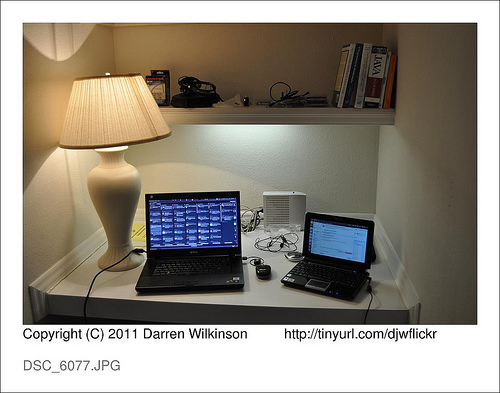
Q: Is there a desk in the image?
A: Yes, there is a desk.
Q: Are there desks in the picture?
A: Yes, there is a desk.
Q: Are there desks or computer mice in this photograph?
A: Yes, there is a desk.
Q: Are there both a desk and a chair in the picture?
A: No, there is a desk but no chairs.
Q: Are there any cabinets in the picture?
A: No, there are no cabinets.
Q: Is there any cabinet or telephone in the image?
A: No, there are no cabinets or phones.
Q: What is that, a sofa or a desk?
A: That is a desk.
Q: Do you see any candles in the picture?
A: No, there are no candles.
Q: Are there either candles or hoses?
A: No, there are no candles or hoses.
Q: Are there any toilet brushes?
A: No, there are no toilet brushes.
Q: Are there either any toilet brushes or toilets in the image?
A: No, there are no toilet brushes or toilets.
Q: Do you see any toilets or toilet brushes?
A: No, there are no toilet brushes or toilets.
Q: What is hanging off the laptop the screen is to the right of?
A: The wire is hanging off the laptop computer.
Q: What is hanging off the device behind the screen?
A: The wire is hanging off the laptop computer.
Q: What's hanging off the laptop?
A: The wire is hanging off the laptop computer.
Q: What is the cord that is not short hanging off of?
A: The wire is hanging off the laptop.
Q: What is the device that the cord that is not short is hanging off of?
A: The device is a laptop.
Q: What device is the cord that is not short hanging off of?
A: The wire is hanging off the laptop.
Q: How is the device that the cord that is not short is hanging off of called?
A: The device is a laptop.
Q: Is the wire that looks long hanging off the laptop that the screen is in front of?
A: Yes, the wire is hanging off the laptop.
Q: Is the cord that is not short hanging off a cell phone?
A: No, the cord is hanging off the laptop.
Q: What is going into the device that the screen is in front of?
A: The cord is going into the laptop.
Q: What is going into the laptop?
A: The cord is going into the laptop.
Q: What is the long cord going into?
A: The cord is going into the laptop.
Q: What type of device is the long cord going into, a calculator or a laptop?
A: The wire is going into a laptop.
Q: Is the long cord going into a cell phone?
A: No, the wire is going into the laptop.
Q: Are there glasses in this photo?
A: No, there are no glasses.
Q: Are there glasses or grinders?
A: No, there are no glasses or grinders.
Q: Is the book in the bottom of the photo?
A: No, the book is in the top of the image.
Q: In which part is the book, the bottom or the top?
A: The book is in the top of the image.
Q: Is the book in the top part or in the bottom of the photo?
A: The book is in the top of the image.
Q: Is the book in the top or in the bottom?
A: The book is in the top of the image.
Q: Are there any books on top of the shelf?
A: Yes, there is a book on top of the shelf.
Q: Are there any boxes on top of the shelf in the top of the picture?
A: No, there is a book on top of the shelf.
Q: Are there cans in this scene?
A: No, there are no cans.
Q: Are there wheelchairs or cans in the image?
A: No, there are no cans or wheelchairs.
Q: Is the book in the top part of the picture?
A: Yes, the book is in the top of the image.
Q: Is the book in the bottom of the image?
A: No, the book is in the top of the image.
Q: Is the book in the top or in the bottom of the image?
A: The book is in the top of the image.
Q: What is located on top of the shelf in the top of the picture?
A: The book is on top of the shelf.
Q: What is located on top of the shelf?
A: The book is on top of the shelf.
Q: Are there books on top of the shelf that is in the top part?
A: Yes, there is a book on top of the shelf.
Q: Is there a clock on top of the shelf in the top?
A: No, there is a book on top of the shelf.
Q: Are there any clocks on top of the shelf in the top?
A: No, there is a book on top of the shelf.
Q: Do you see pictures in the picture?
A: No, there are no pictures.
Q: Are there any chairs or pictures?
A: No, there are no pictures or chairs.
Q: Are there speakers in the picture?
A: No, there are no speakers.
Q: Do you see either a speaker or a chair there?
A: No, there are no speakers or chairs.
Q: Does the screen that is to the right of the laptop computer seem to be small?
A: Yes, the screen is small.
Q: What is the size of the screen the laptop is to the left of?
A: The screen is small.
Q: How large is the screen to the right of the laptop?
A: The screen is small.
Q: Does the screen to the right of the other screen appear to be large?
A: No, the screen is small.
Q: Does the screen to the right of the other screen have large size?
A: No, the screen is small.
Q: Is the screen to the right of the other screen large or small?
A: The screen is small.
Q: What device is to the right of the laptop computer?
A: The device is a screen.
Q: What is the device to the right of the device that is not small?
A: The device is a screen.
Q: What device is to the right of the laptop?
A: The device is a screen.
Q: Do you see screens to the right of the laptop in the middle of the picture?
A: Yes, there is a screen to the right of the laptop.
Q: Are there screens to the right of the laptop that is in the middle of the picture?
A: Yes, there is a screen to the right of the laptop.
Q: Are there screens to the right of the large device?
A: Yes, there is a screen to the right of the laptop.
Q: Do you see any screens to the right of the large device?
A: Yes, there is a screen to the right of the laptop.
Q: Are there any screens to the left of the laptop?
A: No, the screen is to the right of the laptop.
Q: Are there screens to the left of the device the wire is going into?
A: No, the screen is to the right of the laptop.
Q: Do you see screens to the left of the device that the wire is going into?
A: No, the screen is to the right of the laptop.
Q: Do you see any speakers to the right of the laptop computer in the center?
A: No, there is a screen to the right of the laptop.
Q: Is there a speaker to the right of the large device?
A: No, there is a screen to the right of the laptop.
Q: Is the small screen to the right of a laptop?
A: Yes, the screen is to the right of a laptop.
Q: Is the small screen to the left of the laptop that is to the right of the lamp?
A: No, the screen is to the right of the laptop.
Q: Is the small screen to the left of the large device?
A: No, the screen is to the right of the laptop.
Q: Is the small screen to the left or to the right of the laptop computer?
A: The screen is to the right of the laptop computer.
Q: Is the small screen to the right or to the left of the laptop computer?
A: The screen is to the right of the laptop computer.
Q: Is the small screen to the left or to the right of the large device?
A: The screen is to the right of the laptop computer.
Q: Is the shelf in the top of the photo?
A: Yes, the shelf is in the top of the image.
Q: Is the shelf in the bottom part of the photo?
A: No, the shelf is in the top of the image.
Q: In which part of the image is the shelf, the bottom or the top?
A: The shelf is in the top of the image.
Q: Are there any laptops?
A: Yes, there is a laptop.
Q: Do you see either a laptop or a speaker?
A: Yes, there is a laptop.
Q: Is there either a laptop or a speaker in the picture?
A: Yes, there is a laptop.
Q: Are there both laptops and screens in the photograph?
A: Yes, there are both a laptop and a screen.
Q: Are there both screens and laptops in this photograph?
A: Yes, there are both a laptop and a screen.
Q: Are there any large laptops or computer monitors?
A: Yes, there is a large laptop.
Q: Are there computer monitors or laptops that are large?
A: Yes, the laptop is large.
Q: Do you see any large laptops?
A: Yes, there is a large laptop.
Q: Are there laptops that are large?
A: Yes, there is a laptop that is large.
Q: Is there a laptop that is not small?
A: Yes, there is a large laptop.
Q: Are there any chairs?
A: No, there are no chairs.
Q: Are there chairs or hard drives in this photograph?
A: No, there are no chairs or hard drives.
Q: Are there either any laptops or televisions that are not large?
A: No, there is a laptop but it is large.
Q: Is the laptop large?
A: Yes, the laptop is large.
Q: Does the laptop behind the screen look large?
A: Yes, the laptop is large.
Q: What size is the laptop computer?
A: The laptop computer is large.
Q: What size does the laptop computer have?
A: The laptop computer has large size.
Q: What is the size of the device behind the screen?
A: The laptop computer is large.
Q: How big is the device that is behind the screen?
A: The laptop is large.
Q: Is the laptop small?
A: No, the laptop is large.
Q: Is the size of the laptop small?
A: No, the laptop is large.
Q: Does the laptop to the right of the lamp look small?
A: No, the laptop computer is large.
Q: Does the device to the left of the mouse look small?
A: No, the laptop computer is large.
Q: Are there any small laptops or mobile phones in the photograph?
A: No, there is a laptop but it is large.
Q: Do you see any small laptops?
A: No, there is a laptop but it is large.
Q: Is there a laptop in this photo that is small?
A: No, there is a laptop but it is large.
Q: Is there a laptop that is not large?
A: No, there is a laptop but it is large.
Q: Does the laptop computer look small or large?
A: The laptop computer is large.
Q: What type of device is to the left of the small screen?
A: The device is a laptop.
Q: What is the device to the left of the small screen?
A: The device is a laptop.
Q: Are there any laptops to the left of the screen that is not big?
A: Yes, there is a laptop to the left of the screen.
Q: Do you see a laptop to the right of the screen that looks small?
A: No, the laptop is to the left of the screen.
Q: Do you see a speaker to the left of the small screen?
A: No, there is a laptop to the left of the screen.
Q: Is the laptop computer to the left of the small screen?
A: Yes, the laptop computer is to the left of the screen.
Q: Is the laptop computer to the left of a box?
A: No, the laptop computer is to the left of the screen.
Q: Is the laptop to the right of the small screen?
A: No, the laptop is to the left of the screen.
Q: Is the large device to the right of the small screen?
A: No, the laptop is to the left of the screen.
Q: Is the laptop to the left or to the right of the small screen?
A: The laptop is to the left of the screen.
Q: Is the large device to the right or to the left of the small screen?
A: The laptop is to the left of the screen.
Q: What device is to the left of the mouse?
A: The device is a laptop.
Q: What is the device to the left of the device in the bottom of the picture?
A: The device is a laptop.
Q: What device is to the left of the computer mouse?
A: The device is a laptop.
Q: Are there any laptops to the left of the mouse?
A: Yes, there is a laptop to the left of the mouse.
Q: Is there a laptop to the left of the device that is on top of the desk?
A: Yes, there is a laptop to the left of the mouse.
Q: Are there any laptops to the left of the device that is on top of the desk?
A: Yes, there is a laptop to the left of the mouse.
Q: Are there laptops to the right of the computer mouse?
A: No, the laptop is to the left of the computer mouse.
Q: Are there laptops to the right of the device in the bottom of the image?
A: No, the laptop is to the left of the computer mouse.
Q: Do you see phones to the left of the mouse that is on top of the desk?
A: No, there is a laptop to the left of the computer mouse.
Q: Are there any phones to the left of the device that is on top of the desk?
A: No, there is a laptop to the left of the computer mouse.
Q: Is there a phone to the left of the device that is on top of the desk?
A: No, there is a laptop to the left of the computer mouse.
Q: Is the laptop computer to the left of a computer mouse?
A: Yes, the laptop computer is to the left of a computer mouse.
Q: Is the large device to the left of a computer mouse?
A: Yes, the laptop computer is to the left of a computer mouse.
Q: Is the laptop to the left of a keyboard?
A: No, the laptop is to the left of a computer mouse.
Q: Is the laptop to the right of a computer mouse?
A: No, the laptop is to the left of a computer mouse.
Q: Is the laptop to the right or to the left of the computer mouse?
A: The laptop is to the left of the computer mouse.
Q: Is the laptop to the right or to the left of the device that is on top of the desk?
A: The laptop is to the left of the computer mouse.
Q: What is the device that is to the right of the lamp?
A: The device is a laptop.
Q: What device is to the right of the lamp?
A: The device is a laptop.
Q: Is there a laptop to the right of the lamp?
A: Yes, there is a laptop to the right of the lamp.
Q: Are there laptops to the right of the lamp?
A: Yes, there is a laptop to the right of the lamp.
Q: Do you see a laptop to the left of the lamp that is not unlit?
A: No, the laptop is to the right of the lamp.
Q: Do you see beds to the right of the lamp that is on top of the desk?
A: No, there is a laptop to the right of the lamp.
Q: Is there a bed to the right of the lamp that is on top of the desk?
A: No, there is a laptop to the right of the lamp.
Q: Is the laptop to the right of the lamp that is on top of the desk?
A: Yes, the laptop is to the right of the lamp.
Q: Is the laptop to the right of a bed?
A: No, the laptop is to the right of the lamp.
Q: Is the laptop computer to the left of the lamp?
A: No, the laptop computer is to the right of the lamp.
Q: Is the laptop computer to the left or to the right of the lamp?
A: The laptop computer is to the right of the lamp.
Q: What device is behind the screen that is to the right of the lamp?
A: The device is a laptop.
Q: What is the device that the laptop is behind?
A: The device is a screen.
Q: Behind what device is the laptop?
A: The laptop is behind the screen.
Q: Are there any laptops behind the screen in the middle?
A: Yes, there is a laptop behind the screen.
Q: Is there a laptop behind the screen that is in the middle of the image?
A: Yes, there is a laptop behind the screen.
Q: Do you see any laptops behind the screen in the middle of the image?
A: Yes, there is a laptop behind the screen.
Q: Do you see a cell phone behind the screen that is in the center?
A: No, there is a laptop behind the screen.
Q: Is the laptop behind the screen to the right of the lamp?
A: Yes, the laptop is behind the screen.